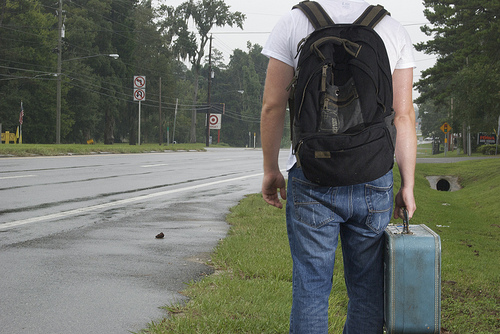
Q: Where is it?
A: This is at the road.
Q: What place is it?
A: It is a road.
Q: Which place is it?
A: It is a road.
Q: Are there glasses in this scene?
A: No, there are no glasses.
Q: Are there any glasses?
A: No, there are no glasses.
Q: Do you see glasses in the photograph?
A: No, there are no glasses.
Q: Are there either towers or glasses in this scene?
A: No, there are no glasses or towers.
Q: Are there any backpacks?
A: Yes, there is a backpack.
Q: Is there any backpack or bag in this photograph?
A: Yes, there is a backpack.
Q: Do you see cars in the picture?
A: No, there are no cars.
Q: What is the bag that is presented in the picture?
A: The bag is a backpack.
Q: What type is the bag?
A: The bag is a backpack.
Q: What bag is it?
A: The bag is a backpack.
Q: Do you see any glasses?
A: No, there are no glasses.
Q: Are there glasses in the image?
A: No, there are no glasses.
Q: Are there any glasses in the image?
A: No, there are no glasses.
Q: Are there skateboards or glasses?
A: No, there are no glasses or skateboards.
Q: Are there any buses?
A: No, there are no buses.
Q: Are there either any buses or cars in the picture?
A: No, there are no buses or cars.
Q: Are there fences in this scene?
A: No, there are no fences.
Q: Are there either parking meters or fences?
A: No, there are no fences or parking meters.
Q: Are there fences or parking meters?
A: No, there are no fences or parking meters.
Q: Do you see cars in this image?
A: No, there are no cars.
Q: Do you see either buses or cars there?
A: No, there are no cars or buses.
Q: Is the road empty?
A: Yes, the road is empty.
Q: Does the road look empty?
A: Yes, the road is empty.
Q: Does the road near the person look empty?
A: Yes, the road is empty.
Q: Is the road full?
A: No, the road is empty.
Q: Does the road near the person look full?
A: No, the road is empty.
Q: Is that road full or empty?
A: The road is empty.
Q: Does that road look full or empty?
A: The road is empty.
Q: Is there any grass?
A: Yes, there is grass.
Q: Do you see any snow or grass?
A: Yes, there is grass.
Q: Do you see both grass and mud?
A: No, there is grass but no mud.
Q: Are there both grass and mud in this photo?
A: No, there is grass but no mud.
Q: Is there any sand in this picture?
A: No, there is no sand.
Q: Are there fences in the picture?
A: No, there are no fences.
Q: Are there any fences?
A: No, there are no fences.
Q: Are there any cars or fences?
A: No, there are no fences or cars.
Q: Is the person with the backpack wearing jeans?
A: Yes, the person is wearing jeans.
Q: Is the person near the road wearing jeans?
A: Yes, the person is wearing jeans.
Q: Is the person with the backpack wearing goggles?
A: No, the person is wearing jeans.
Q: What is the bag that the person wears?
A: The bag is a backpack.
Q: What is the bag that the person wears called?
A: The bag is a backpack.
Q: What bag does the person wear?
A: The person wears a backpack.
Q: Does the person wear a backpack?
A: Yes, the person wears a backpack.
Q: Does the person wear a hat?
A: No, the person wears a backpack.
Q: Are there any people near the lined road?
A: Yes, there is a person near the road.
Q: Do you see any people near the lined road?
A: Yes, there is a person near the road.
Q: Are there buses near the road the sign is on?
A: No, there is a person near the road.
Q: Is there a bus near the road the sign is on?
A: No, there is a person near the road.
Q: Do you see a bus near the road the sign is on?
A: No, there is a person near the road.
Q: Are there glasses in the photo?
A: No, there are no glasses.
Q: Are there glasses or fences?
A: No, there are no glasses or fences.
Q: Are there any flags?
A: Yes, there is a flag.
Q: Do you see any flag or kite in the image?
A: Yes, there is a flag.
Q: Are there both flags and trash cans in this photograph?
A: No, there is a flag but no trash cans.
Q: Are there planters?
A: No, there are no planters.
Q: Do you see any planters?
A: No, there are no planters.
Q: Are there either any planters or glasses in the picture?
A: No, there are no planters or glasses.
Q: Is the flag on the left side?
A: Yes, the flag is on the left of the image.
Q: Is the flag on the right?
A: No, the flag is on the left of the image.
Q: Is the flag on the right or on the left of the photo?
A: The flag is on the left of the image.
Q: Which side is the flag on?
A: The flag is on the left of the image.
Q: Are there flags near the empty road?
A: Yes, there is a flag near the road.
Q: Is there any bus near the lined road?
A: No, there is a flag near the road.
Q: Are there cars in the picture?
A: No, there are no cars.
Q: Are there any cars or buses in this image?
A: No, there are no cars or buses.